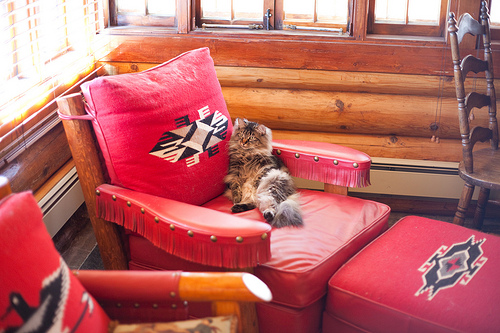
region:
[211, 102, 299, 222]
a cat lying in a chair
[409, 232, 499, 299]
a southwestern pattern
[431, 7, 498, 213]
a brown wooden chair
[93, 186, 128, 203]
brass furniture screws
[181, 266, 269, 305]
a wooden arm rest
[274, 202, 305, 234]
a fluffy gray tail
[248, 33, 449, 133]
maple logs in the wall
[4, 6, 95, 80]
light filtering through blinds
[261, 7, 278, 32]
a metal latch on the windowsill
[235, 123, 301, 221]
the cat is grey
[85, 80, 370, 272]
the chair is wooden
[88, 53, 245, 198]
the cushion is red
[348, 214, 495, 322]
the cushion is red in color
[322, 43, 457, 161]
the wall is made of wood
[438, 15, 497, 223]
the chair is wooden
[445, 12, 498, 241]
the chair is brown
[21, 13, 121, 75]
the blinds are open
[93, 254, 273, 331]
the armrest is wooden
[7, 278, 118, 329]
bird is on the cushion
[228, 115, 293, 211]
this is a cat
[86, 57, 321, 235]
this is a chair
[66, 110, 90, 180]
the chair is brown in color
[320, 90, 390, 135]
the wall is brown in color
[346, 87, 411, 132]
the wall is wooden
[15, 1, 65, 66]
this is the window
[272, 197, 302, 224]
this is the tail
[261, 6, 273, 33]
this is the lock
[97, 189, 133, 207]
brass furniture nails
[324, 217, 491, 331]
a red ottoman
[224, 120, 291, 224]
a fluffy gray cat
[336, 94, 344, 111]
a dark spot on the log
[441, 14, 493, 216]
a brown wooden chair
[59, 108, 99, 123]
a strap on the seat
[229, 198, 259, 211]
a small black cat paw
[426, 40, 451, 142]
a brown pull string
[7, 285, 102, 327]
a bird pattern on the chair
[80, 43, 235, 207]
Bright red chair cushsion with a southwest design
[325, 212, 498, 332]
Bright red ottoman with a southwest design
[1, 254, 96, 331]
Black and white southwest bird design on a cushion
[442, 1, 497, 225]
Brown wood chair with a tall back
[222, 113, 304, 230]
Fluffy brown and tan cat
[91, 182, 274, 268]
Red fringe on the arm of a chair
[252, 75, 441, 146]
Knolls in wood of a log house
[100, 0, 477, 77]
Four narrow windows with wooden frames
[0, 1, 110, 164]
Venetian blinds in a sunny window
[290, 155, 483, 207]
Baseboard style tan colored heater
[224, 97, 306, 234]
a black white and grey cat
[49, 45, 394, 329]
cat in a red chair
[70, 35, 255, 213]
red cushion with a black symbol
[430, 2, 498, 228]
a brown wooden chair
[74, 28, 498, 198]
a brown wooden wall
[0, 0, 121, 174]
A window with open blinds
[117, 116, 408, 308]
Cat on a red leather cushion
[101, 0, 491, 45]
row of four windows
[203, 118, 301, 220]
A cat is sleeping in the chair.